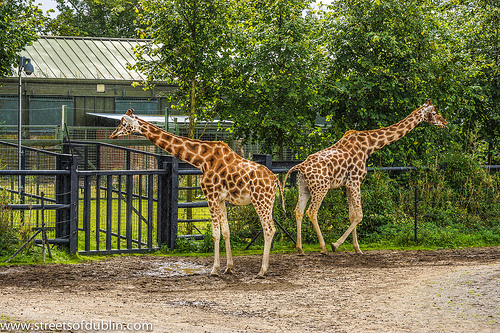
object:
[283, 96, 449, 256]
giraffe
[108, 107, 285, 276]
giraffe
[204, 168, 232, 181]
fur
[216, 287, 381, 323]
sand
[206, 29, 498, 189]
trees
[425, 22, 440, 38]
leaves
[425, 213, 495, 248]
grass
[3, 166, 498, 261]
fence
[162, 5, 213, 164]
tree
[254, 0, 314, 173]
tree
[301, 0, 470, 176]
tree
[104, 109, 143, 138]
head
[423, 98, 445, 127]
head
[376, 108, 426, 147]
neck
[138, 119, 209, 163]
neck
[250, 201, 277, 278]
legs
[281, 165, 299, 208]
tail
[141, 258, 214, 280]
mud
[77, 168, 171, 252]
gate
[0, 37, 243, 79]
roof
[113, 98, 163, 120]
window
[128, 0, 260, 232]
tree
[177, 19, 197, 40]
leaves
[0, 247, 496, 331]
ground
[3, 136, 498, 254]
gate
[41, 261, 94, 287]
mud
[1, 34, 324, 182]
building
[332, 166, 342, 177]
spots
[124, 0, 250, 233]
tree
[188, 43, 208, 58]
leaves